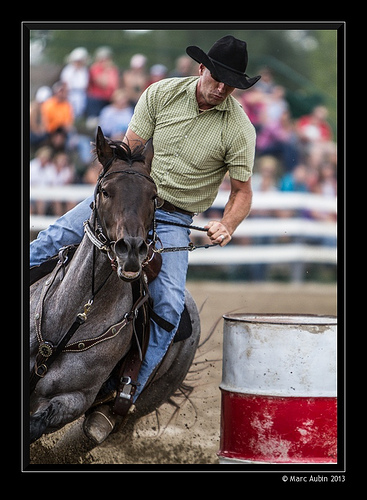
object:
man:
[30, 34, 257, 444]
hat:
[183, 32, 262, 92]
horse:
[29, 125, 201, 449]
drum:
[220, 308, 337, 463]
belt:
[154, 192, 194, 217]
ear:
[141, 135, 155, 169]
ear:
[94, 123, 115, 167]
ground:
[80, 281, 339, 465]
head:
[196, 37, 253, 105]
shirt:
[128, 75, 258, 214]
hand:
[203, 219, 234, 248]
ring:
[217, 234, 226, 242]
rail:
[28, 179, 338, 213]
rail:
[28, 213, 336, 240]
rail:
[185, 243, 335, 267]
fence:
[29, 181, 337, 270]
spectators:
[40, 77, 75, 129]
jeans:
[29, 190, 194, 406]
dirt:
[145, 415, 213, 465]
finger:
[220, 236, 232, 247]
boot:
[80, 393, 120, 444]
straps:
[83, 220, 109, 259]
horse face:
[97, 164, 156, 282]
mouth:
[116, 265, 143, 280]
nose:
[115, 234, 151, 268]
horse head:
[90, 124, 160, 283]